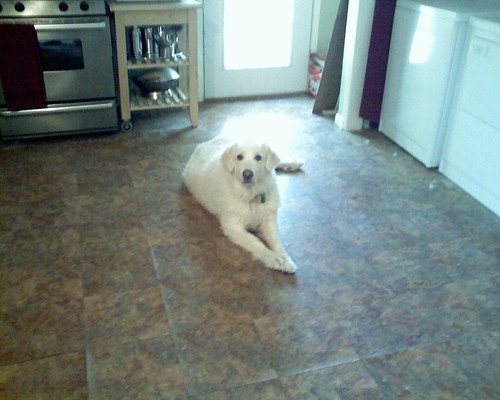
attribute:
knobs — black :
[13, 10, 140, 38]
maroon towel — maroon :
[0, 25, 49, 115]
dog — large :
[185, 126, 336, 288]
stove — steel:
[0, 0, 134, 141]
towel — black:
[4, 11, 68, 115]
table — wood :
[68, 1, 218, 96]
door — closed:
[174, 0, 320, 96]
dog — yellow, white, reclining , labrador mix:
[181, 130, 303, 271]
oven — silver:
[2, 2, 128, 137]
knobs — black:
[1, 1, 92, 14]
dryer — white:
[386, 0, 468, 179]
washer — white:
[382, 0, 448, 168]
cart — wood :
[92, 6, 234, 131]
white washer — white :
[384, 1, 464, 161]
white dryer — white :
[438, 12, 499, 218]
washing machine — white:
[377, 0, 470, 171]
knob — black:
[80, 2, 93, 14]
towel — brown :
[4, 20, 49, 111]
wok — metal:
[112, 59, 187, 103]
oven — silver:
[0, 0, 121, 140]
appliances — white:
[375, 4, 470, 169]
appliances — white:
[438, 14, 498, 220]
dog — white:
[174, 120, 312, 258]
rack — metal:
[1, 20, 108, 31]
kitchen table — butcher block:
[112, 2, 211, 137]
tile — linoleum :
[0, 87, 498, 398]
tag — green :
[257, 189, 270, 209]